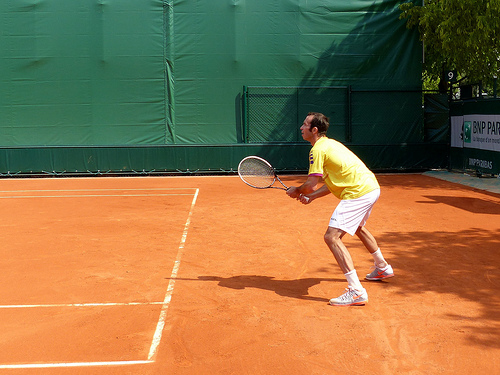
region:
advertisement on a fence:
[441, 108, 498, 153]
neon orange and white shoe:
[361, 262, 397, 280]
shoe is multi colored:
[363, 262, 396, 280]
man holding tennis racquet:
[236, 107, 396, 307]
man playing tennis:
[236, 109, 398, 309]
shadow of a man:
[161, 272, 389, 305]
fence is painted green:
[241, 81, 498, 143]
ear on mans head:
[309, 124, 320, 135]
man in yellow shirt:
[283, 108, 398, 308]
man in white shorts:
[282, 110, 397, 309]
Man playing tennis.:
[230, 101, 406, 318]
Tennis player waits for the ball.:
[230, 93, 407, 310]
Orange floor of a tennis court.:
[8, 141, 216, 362]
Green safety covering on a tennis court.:
[15, 6, 271, 151]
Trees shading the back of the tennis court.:
[402, 6, 498, 287]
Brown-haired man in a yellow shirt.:
[231, 94, 399, 321]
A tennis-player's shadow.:
[156, 269, 343, 326]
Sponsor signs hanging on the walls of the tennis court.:
[445, 110, 497, 186]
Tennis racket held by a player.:
[224, 152, 311, 206]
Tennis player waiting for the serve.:
[224, 82, 431, 323]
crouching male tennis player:
[282, 111, 395, 311]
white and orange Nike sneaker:
[327, 288, 369, 305]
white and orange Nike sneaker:
[363, 265, 393, 282]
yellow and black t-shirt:
[305, 140, 375, 196]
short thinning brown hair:
[307, 111, 327, 134]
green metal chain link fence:
[244, 82, 462, 149]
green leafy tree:
[394, 2, 498, 97]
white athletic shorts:
[327, 194, 380, 230]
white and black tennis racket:
[235, 155, 307, 207]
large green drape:
[3, 1, 423, 149]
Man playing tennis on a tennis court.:
[239, 97, 419, 318]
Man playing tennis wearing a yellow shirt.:
[299, 137, 379, 198]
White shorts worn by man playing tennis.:
[336, 195, 370, 236]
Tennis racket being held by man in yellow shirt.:
[231, 150, 315, 221]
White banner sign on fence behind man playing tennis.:
[449, 110, 498, 157]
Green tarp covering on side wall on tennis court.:
[8, 0, 416, 177]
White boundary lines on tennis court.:
[6, 188, 198, 365]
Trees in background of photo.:
[397, 0, 497, 100]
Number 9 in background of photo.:
[439, 62, 456, 83]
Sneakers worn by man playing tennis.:
[328, 265, 415, 307]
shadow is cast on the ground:
[127, 218, 349, 361]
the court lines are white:
[90, 193, 223, 353]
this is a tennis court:
[3, 158, 460, 371]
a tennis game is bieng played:
[18, 75, 428, 362]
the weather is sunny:
[33, 171, 222, 371]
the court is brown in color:
[39, 173, 276, 372]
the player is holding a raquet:
[212, 137, 397, 312]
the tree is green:
[413, 6, 497, 68]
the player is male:
[231, 111, 411, 315]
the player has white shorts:
[237, 113, 428, 318]